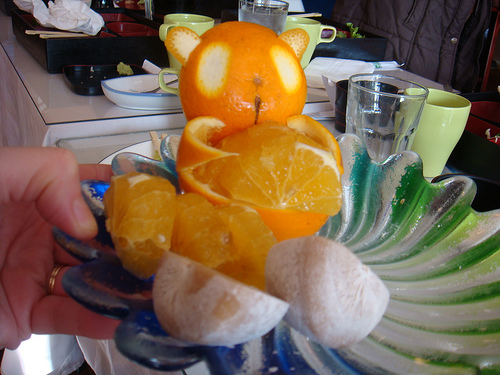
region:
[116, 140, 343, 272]
slices of an orange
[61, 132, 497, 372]
blue and green serving bowl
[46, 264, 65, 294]
a gold band on the finger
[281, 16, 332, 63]
a yellow coffee cup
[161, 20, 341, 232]
an orange shaped like a bear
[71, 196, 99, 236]
no nail polish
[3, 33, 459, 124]
glass topper on the table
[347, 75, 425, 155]
a glass drinking cup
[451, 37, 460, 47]
a silver jacket button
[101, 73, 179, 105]
a blue accent on the white dish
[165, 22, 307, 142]
An orange made to look like an animal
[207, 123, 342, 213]
AN orange cut in half and peeled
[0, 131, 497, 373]
A hand holding a bowl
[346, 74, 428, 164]
An empty clear glass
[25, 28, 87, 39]
A pair of chopsticks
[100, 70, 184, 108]
A plate with a fork in it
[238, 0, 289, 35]
A glass of cold water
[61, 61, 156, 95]
A black plate with food leftovers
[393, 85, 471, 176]
A yellow pasteled cup on the table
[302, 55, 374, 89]
A stack of white napkins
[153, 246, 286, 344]
A slice of an orange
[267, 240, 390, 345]
An orange that was sliced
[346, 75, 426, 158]
Glass on a table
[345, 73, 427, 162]
Clear glass on a counter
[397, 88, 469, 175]
A lime green cup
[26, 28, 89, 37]
Utencils on a counter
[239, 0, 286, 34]
A glass with water in it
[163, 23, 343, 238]
A collective group of oranges shaped as a bear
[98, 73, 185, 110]
A white dish on a counter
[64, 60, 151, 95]
A small plate on a counter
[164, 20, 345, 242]
Oranges made to look like a little bear.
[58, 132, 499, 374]
The oranges are inside of a leaf shaped dish.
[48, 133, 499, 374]
The dish is green, white and blue.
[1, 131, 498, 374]
A person's hand holding the dish.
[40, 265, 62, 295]
A wedding ring on the person's finger.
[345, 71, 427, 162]
A clear empty glass behind the leaf dish.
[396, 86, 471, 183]
A green cup next to the glass.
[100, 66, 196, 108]
A blue and white dish with a fork lying in it.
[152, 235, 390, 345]
Two halves of a peeled orange.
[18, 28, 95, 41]
Chopsticks in a black tray.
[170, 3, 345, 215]
fruit in the shape of a bear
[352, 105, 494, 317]
blue and green serving plate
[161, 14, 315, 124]
cute bear made of an orange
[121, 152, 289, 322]
orange slices on a plate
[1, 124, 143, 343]
this person is wearing wedding rings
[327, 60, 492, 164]
cups on the table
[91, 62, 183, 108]
blue and white bowl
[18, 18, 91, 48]
chopsticks in a box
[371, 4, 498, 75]
brown coat in the back ground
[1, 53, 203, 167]
white table cloth